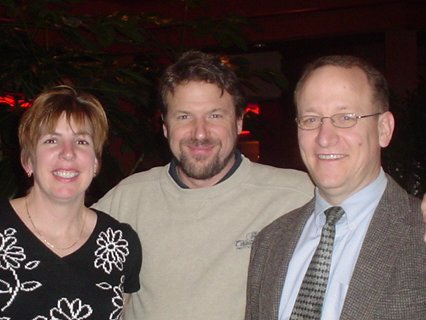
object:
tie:
[289, 206, 344, 318]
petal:
[116, 239, 127, 246]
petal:
[111, 226, 119, 241]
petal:
[99, 228, 108, 242]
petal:
[94, 245, 104, 254]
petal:
[108, 250, 111, 260]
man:
[291, 59, 421, 318]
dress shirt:
[297, 194, 374, 314]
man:
[152, 52, 245, 246]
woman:
[12, 88, 132, 317]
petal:
[3, 233, 18, 249]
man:
[151, 57, 260, 215]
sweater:
[144, 182, 260, 307]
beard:
[179, 137, 222, 178]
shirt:
[282, 177, 387, 318]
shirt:
[104, 167, 306, 318]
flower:
[92, 224, 132, 262]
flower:
[0, 227, 38, 317]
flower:
[48, 297, 95, 318]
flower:
[95, 275, 122, 318]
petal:
[113, 227, 120, 240]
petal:
[71, 295, 81, 315]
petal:
[112, 295, 124, 307]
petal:
[106, 250, 114, 263]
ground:
[353, 117, 394, 143]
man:
[241, 63, 412, 260]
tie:
[279, 202, 363, 313]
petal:
[113, 228, 123, 238]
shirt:
[3, 192, 143, 318]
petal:
[5, 245, 23, 253]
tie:
[284, 197, 372, 318]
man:
[275, 54, 416, 315]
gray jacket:
[260, 201, 415, 316]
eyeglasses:
[292, 111, 383, 130]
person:
[243, 57, 424, 317]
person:
[83, 49, 317, 317]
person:
[0, 83, 142, 317]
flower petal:
[91, 230, 134, 271]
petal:
[113, 240, 128, 257]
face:
[287, 79, 378, 188]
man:
[240, 52, 424, 318]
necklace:
[22, 194, 88, 249]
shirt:
[101, 142, 322, 317]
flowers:
[0, 225, 25, 269]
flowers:
[47, 294, 93, 318]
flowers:
[107, 273, 126, 318]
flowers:
[92, 227, 130, 272]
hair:
[181, 158, 218, 173]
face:
[153, 87, 247, 170]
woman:
[3, 81, 153, 318]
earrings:
[25, 170, 98, 178]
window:
[21, 165, 33, 180]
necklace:
[23, 198, 99, 255]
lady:
[0, 77, 141, 313]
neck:
[25, 188, 85, 228]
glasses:
[292, 111, 382, 128]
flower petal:
[2, 254, 20, 270]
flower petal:
[6, 251, 26, 261]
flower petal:
[0, 237, 15, 250]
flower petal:
[57, 297, 72, 318]